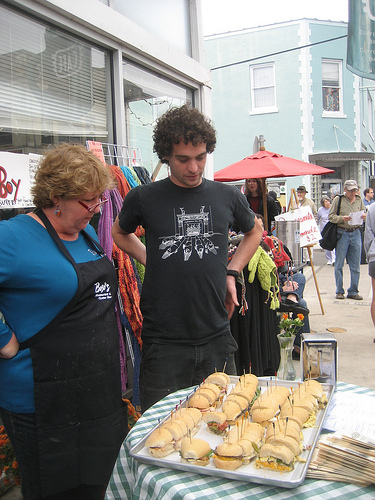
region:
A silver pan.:
[129, 372, 335, 483]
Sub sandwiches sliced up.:
[151, 370, 321, 471]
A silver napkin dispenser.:
[301, 332, 337, 389]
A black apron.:
[15, 206, 127, 491]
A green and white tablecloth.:
[95, 375, 368, 496]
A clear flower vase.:
[277, 332, 292, 377]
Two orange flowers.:
[274, 311, 300, 335]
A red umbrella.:
[210, 150, 330, 180]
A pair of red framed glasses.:
[75, 197, 113, 212]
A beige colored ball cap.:
[343, 179, 359, 191]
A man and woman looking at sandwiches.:
[0, 102, 325, 466]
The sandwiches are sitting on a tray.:
[137, 367, 326, 483]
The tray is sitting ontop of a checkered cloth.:
[130, 365, 332, 492]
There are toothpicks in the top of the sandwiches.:
[150, 367, 315, 472]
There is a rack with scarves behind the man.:
[88, 142, 153, 425]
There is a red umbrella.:
[211, 121, 331, 196]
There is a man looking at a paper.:
[326, 179, 367, 298]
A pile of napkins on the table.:
[307, 428, 372, 482]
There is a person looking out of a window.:
[319, 81, 338, 113]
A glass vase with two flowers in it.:
[277, 310, 302, 379]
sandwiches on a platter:
[53, 295, 371, 468]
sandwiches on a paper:
[157, 320, 324, 494]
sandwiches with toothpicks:
[126, 297, 374, 476]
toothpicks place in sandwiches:
[118, 293, 368, 496]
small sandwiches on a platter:
[134, 309, 361, 488]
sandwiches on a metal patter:
[119, 292, 369, 488]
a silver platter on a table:
[113, 307, 358, 492]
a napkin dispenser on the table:
[277, 314, 350, 433]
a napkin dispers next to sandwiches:
[282, 308, 365, 420]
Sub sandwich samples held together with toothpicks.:
[128, 374, 328, 483]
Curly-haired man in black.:
[112, 107, 265, 372]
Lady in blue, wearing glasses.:
[1, 141, 125, 434]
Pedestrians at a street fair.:
[296, 176, 373, 334]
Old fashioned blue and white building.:
[203, 13, 373, 181]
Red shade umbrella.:
[214, 127, 334, 240]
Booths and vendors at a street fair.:
[0, 135, 332, 373]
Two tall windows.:
[2, 2, 150, 143]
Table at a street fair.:
[105, 317, 373, 498]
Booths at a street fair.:
[227, 189, 330, 328]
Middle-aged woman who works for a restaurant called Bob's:
[0, 141, 124, 499]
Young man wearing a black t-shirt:
[107, 103, 268, 422]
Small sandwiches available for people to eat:
[126, 353, 336, 488]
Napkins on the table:
[299, 405, 373, 485]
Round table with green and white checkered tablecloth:
[101, 365, 373, 498]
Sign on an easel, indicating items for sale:
[269, 185, 329, 317]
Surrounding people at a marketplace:
[222, 167, 372, 344]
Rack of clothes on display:
[60, 135, 159, 429]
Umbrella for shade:
[207, 130, 336, 303]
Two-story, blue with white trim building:
[104, 13, 373, 272]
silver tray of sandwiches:
[124, 356, 338, 491]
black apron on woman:
[13, 204, 131, 499]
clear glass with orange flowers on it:
[271, 306, 307, 382]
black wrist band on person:
[226, 263, 242, 281]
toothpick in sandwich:
[220, 357, 226, 376]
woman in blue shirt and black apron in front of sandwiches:
[1, 136, 130, 496]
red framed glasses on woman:
[73, 189, 112, 215]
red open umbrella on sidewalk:
[212, 133, 337, 243]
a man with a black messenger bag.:
[320, 181, 368, 306]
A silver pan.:
[149, 371, 315, 496]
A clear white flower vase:
[278, 332, 298, 381]